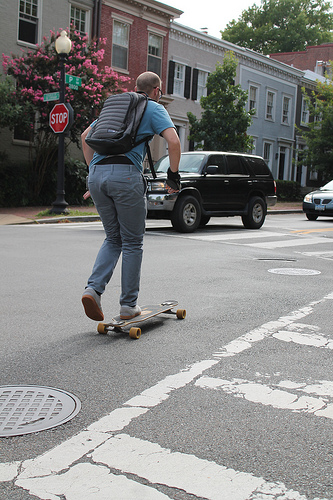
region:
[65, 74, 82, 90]
green and white street sign on a pole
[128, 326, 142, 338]
dark yellow wheel of a skateboard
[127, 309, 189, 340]
two dark yellow skateboard wheels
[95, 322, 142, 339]
two dark yellow skateboard wheels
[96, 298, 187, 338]
black skateboard with dark yellow wheels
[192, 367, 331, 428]
cracked white line on a street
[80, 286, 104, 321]
shoe with an orange bottom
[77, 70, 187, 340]
man riding his skateboard on a street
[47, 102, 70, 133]
red and white stop sign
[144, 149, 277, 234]
large black vehicle on a street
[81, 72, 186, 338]
Man skateboarding down the street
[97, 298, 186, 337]
Black skateboard with yellow wheels being ridden by a man in the street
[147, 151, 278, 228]
Black sport utility vehicle driving down a city street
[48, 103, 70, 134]
Red STOP sign at the intersection of city street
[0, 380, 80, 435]
Round metal manhole cover behind a skateboarder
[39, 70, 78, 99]
Two green street signs on a light pole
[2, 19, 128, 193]
Tree with pink flowers in the city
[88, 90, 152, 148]
Gray backpack on a man skateboarding down a street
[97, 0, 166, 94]
Second story of a red brick building with two windows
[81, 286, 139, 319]
Gray shoes with orange soles of a skateboarder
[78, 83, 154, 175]
bag of the person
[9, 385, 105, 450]
a round whole in ground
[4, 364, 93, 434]
a dig in the ground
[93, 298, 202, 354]
a small skating machine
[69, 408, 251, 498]
a white line in road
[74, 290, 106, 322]
shoe of the person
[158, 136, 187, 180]
hand of the person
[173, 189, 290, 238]
two wheel of the car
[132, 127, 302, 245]
a car placed in road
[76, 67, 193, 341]
Man riding skateboard down street.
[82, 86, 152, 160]
Man carrying gray backpack on back.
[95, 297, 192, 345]
Skateboard under man's foot.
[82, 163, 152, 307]
Man dressed in blue jeans.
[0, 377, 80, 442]
Manhole cover on street.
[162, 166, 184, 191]
Man wearing fingerless black glove.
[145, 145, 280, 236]
Black SUV stopped in traffic.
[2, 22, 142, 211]
Pink flowers blooming on tree.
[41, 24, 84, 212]
Lamp post standing on sidewalk.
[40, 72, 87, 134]
Stop sign and street name signs mounted on lamp post.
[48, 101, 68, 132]
red stop sign on street corner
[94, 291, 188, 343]
skateboard with yellow wheels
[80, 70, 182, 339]
man riding skateboard on street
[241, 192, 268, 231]
black tire on truck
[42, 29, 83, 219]
pole on street with lamp and signs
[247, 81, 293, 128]
three windows on front of building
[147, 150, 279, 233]
black truck at stop sign on street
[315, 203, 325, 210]
license plate on front of car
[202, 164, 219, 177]
side mirror on truck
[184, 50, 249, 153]
green tree on street